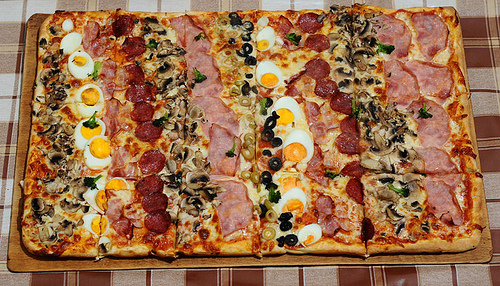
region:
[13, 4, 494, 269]
Sliced pizza sitting on cutting board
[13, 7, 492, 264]
Brown cutting board holding pizza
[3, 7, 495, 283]
Plaid table cloth holding pizza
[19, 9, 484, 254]
Cooked pizza cut into 20 slices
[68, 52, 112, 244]
Hard boiled eggs sitting on pizza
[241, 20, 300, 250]
Line of black olives on pizza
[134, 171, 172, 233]
Pepperoni slices on pizza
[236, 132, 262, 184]
Green olives on pizza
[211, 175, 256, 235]
Ham sliced on pizza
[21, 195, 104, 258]
Slice of cooked pizza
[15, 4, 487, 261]
large rectangular pizza with toppings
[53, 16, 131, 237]
row of hard boiled eggs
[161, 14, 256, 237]
row of canadian bacon slices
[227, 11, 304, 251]
row of black olives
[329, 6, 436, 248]
row of sliced mushrooms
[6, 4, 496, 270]
wooden rectangular cutting board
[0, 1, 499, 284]
red plaid table cloth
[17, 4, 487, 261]
thin rectangular pizza crust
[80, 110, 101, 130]
small piece of broccoli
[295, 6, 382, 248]
row of pepperoni slices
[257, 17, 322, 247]
egg slices on pizza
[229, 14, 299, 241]
black and green olives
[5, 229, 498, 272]
wooden board under pizza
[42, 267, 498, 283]
plaid table cloth under pizza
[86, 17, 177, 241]
row of meats on pizza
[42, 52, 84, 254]
mushrooms on pizza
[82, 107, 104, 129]
small broccoli florets on pizza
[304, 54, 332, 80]
round pepperoni slice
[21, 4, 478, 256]
meat and veggie pizza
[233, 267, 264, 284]
chocolate brown check on table cloth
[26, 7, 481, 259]
A pizza covered in toppings.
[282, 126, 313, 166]
A egg on the pizza.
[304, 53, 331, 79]
A pepperoni on the pizza.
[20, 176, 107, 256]
A slice of pizza with mushrooms and egg.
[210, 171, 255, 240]
Canadian bacon on the pizza.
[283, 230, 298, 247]
A black olive on the pizza.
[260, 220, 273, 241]
A green olive on a pizza slice.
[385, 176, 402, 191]
A green broccoli on the pizza.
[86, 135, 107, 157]
The yolk of a egg.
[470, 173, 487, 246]
Crust of a pizza slice.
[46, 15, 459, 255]
this is a pizza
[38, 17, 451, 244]
the pizza is big in size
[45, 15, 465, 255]
the pizza is rectangular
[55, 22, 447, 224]
the pizza is spicy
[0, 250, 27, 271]
this is a tray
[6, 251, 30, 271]
the tray is wooden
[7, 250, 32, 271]
the tray is brown in color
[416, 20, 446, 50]
the spice is red in color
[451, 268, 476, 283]
this is the table mat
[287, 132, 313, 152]
the white spice is in the middle